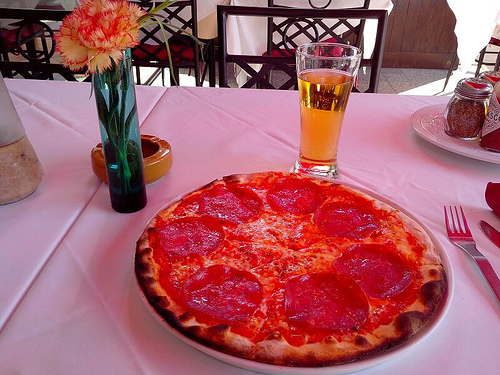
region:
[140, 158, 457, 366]
pizza on a plate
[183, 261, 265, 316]
tomato on a pizza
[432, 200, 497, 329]
utensils on a table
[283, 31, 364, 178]
beer in a glass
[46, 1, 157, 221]
flowers in a vase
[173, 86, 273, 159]
white tablecloth on a table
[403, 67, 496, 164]
spices on a plate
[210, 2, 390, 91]
chair by a table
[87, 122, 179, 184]
ashtray on a table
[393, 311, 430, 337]
burnt part of a crust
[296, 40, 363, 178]
a glass of beer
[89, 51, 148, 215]
a colored glass flower vase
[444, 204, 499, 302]
a silver metal fork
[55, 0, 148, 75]
pink pedals on a flower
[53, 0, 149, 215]
pink flower in a vase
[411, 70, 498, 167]
a plate containing seasoning containers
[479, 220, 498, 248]
a silver metal knife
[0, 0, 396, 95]
a table and chairs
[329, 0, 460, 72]
a brown wall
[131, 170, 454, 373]
pepperoni pizza on a white plate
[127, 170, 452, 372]
pizza on a plate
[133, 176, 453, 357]
pepperoni pizza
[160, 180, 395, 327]
pepperoni on pizza are really large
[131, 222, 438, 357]
crust is a little burnt around edges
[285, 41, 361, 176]
beer in a glass on table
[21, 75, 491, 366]
food is on white table cloth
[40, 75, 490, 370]
wrinkles in table cloth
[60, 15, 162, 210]
carnation in a green vase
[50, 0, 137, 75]
carnation is yellow with red outline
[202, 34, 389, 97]
metal chair at opposite end of table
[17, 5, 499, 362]
a restaurant is serving pizza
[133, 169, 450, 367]
the pizza has extraordinary slices of pepperoni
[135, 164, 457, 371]
the pizza is on a pie plate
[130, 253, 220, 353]
the crust is well done on the edges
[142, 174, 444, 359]
the pizza has been sliced into wedges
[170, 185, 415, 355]
melted cheese is on top of the pizza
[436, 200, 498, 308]
silverware is beside the pie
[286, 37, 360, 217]
a tall glass of beer is next to the pie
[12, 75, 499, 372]
a white tablecloth is on the table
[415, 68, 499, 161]
condiments are on a white plate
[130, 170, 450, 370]
The pizza is pepperoni.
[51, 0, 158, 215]
Flowers are in a glass container.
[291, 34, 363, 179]
Drink is in a glass.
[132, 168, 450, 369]
Pizza is on a plate.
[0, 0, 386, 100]
The chairs have red cushions.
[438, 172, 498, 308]
Utensils are next to the pizza.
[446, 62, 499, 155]
Spices are near the pizza.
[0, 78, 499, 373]
The tablecloth is white.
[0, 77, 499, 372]
The table holds food and drinks.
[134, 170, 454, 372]
The pizza is round.